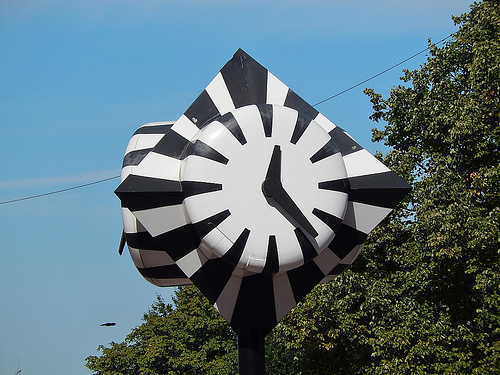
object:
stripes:
[147, 127, 211, 163]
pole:
[236, 335, 267, 375]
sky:
[0, 1, 470, 375]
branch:
[399, 206, 419, 216]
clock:
[179, 101, 355, 273]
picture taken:
[0, 0, 500, 375]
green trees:
[85, 0, 500, 375]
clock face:
[180, 101, 362, 277]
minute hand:
[268, 191, 325, 237]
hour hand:
[261, 143, 294, 184]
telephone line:
[0, 28, 483, 206]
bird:
[99, 319, 117, 328]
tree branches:
[445, 45, 449, 48]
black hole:
[419, 260, 486, 330]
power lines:
[0, 170, 129, 206]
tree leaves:
[375, 94, 381, 98]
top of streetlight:
[5, 367, 26, 374]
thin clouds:
[10, 229, 131, 255]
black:
[234, 66, 261, 103]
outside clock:
[118, 38, 417, 342]